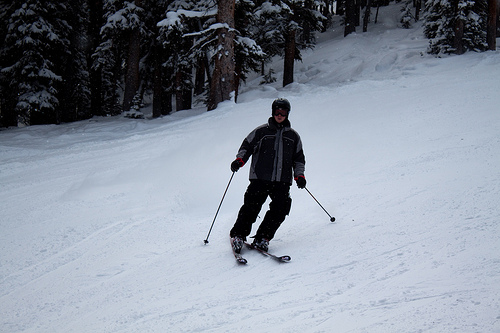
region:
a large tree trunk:
[209, 0, 240, 97]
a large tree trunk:
[280, 2, 295, 86]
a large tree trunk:
[151, 10, 174, 110]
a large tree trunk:
[170, 34, 195, 110]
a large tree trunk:
[193, 31, 209, 93]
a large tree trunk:
[121, 40, 146, 115]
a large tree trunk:
[0, 47, 23, 128]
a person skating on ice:
[198, 91, 340, 288]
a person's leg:
[260, 180, 291, 251]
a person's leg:
[230, 175, 263, 248]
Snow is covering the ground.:
[7, 73, 452, 293]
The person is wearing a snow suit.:
[198, 74, 328, 279]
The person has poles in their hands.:
[212, 135, 327, 250]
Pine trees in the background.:
[6, 4, 310, 104]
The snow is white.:
[351, 136, 463, 286]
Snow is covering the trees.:
[104, 11, 256, 82]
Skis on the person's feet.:
[220, 218, 299, 286]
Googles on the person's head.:
[258, 86, 307, 127]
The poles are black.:
[286, 168, 344, 228]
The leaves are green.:
[73, 18, 184, 97]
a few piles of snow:
[336, 31, 441, 92]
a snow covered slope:
[46, 63, 470, 331]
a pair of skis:
[228, 217, 291, 289]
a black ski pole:
[198, 150, 255, 251]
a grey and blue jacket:
[223, 115, 334, 199]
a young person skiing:
[209, 90, 346, 300]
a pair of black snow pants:
[223, 172, 303, 259]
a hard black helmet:
[262, 86, 307, 123]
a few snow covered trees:
[7, 1, 244, 123]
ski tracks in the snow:
[56, 177, 172, 267]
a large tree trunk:
[343, 0, 358, 35]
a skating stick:
[201, 155, 248, 247]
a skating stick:
[294, 167, 342, 226]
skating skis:
[226, 227, 299, 283]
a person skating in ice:
[190, 91, 357, 296]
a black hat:
[271, 95, 292, 110]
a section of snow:
[362, 119, 440, 229]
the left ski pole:
[293, 172, 352, 229]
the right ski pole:
[148, 142, 282, 262]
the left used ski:
[240, 220, 297, 271]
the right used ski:
[221, 224, 261, 266]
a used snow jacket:
[223, 107, 339, 192]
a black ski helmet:
[270, 92, 295, 118]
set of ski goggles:
[261, 98, 298, 125]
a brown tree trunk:
[273, 27, 308, 103]